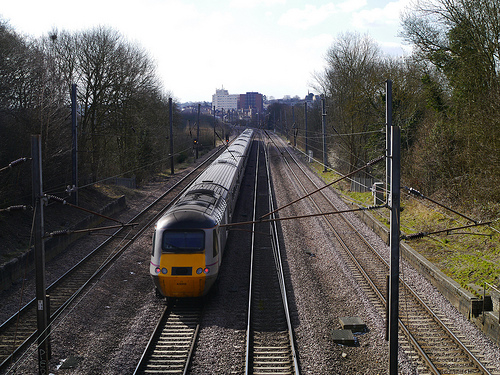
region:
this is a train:
[148, 157, 247, 275]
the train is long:
[150, 134, 251, 291]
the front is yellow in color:
[157, 250, 201, 292]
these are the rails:
[158, 302, 288, 368]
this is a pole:
[366, 246, 417, 373]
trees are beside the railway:
[428, 35, 490, 148]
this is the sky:
[226, 2, 313, 52]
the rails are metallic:
[235, 285, 310, 341]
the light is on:
[199, 263, 209, 276]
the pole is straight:
[374, 209, 417, 276]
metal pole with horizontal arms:
[218, 81, 498, 371]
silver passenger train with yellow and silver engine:
[150, 129, 251, 309]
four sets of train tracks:
[0, 129, 499, 374]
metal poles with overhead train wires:
[0, 77, 497, 373]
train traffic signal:
[192, 138, 197, 145]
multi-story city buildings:
[211, 85, 267, 112]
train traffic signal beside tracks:
[224, 133, 229, 145]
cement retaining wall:
[1, 197, 123, 293]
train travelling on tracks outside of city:
[4, 86, 496, 371]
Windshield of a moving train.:
[160, 230, 207, 253]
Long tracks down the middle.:
[254, 146, 275, 260]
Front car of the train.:
[146, 205, 231, 302]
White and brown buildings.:
[198, 88, 295, 115]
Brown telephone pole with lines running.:
[368, 104, 411, 364]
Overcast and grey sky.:
[188, 28, 303, 78]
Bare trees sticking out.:
[8, 25, 144, 175]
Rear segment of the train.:
[230, 129, 260, 158]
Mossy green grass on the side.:
[410, 196, 490, 295]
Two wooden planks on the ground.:
[323, 306, 368, 361]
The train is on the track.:
[77, 108, 325, 373]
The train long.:
[128, 90, 288, 329]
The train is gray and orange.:
[137, 89, 289, 363]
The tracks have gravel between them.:
[1, 106, 498, 373]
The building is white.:
[204, 79, 239, 131]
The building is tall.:
[210, 81, 240, 120]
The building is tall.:
[234, 82, 267, 127]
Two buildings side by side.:
[206, 70, 275, 127]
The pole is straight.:
[57, 70, 89, 215]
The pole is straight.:
[160, 86, 180, 183]